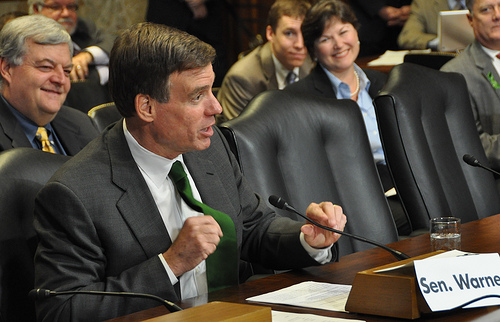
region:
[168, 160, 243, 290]
man wearing green tie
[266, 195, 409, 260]
man holding black microphone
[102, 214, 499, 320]
man sitting at long brown table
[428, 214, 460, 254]
clear glass of water on table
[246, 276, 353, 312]
white piece of paper in front of man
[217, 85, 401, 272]
empty black chair next to man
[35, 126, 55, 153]
man wearing yellow tie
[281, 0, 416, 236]
woman smiling toward man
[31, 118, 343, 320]
man wearing grey suit jacket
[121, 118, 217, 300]
man wearing white shirt under jacket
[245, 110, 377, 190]
a black leather seat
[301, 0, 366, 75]
a lady laughing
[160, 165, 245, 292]
the man has a green tie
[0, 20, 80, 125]
an old smiling man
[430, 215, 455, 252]
a glass of water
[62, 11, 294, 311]
a man giving a speech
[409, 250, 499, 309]
name tag on the table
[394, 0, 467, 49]
a person using a laptop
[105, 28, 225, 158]
neatlly combed black hair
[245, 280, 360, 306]
a paper on the table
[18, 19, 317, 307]
man sitting in front of microphone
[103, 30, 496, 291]
two empty black chairs next to man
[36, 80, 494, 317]
name tag in front of man at table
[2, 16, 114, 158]
man sitting and smiling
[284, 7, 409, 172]
woman sitting and smiling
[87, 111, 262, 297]
white shirt and green necktie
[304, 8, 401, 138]
white pearls around neck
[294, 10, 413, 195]
lady wearing light blue buttondown shirt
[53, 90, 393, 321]
papers on table in front of man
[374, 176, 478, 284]
glass of water on table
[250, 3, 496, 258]
people behind black chairs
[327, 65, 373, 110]
open shirt and pearls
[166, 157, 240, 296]
hand holding green tie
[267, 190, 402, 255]
hand around black microphone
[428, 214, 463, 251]
clear glass of water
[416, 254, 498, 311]
white car with black words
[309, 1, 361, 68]
face of smiling woman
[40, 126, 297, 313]
gray coat over dress shirt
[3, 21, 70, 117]
man with gray hair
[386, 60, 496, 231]
back of black leather chair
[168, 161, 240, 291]
A green tie.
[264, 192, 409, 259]
A microphone.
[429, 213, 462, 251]
A glass of water on a table.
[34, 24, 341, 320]
A man in a dark jacket.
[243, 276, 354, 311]
A piece of paper on a table.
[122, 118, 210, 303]
A white shirt.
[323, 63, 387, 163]
A blue shirt.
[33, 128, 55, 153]
A yellow tie.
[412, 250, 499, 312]
A sign on a table.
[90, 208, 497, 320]
A brown wooden table.